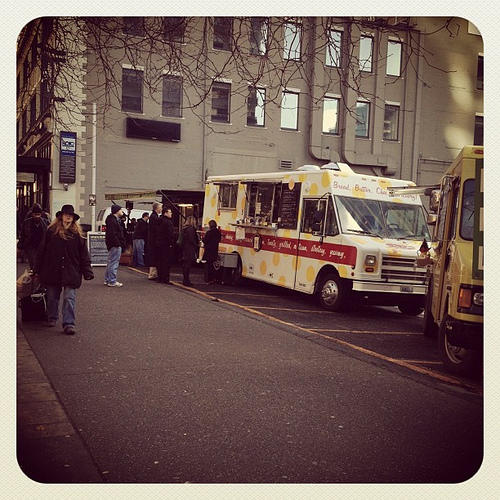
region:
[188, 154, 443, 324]
truck on the ground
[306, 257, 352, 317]
front wheel of a vehicle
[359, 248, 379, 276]
front headlight of a vehicle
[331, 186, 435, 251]
front windshield on a vehicle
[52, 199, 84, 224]
black hat on a persons head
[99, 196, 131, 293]
person with blue pants standing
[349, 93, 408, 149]
windows on a building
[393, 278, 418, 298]
front licence plate on a vehicle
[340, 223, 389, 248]
windshield wiper on a vehicle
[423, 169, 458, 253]
side rear view mirror on a vehicle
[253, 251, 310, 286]
yellow polkadots design on van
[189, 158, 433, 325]
the food vendor van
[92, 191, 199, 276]
a crowd of people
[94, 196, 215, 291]
a line of people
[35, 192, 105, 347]
a woman walking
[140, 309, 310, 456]
the ground is asphalt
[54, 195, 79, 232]
the woman wearing a black hat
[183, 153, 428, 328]
the van has yellow pokadots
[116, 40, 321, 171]
the building behind the van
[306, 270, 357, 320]
the tire on the van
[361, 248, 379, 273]
the head light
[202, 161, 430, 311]
white and yellow truck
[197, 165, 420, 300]
white truck with yellow spots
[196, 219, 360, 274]
red painted stripe on truck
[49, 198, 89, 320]
woman wearing black hat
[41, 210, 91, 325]
woman with long blond hair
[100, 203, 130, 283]
man standing in line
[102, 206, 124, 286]
man wearing blue jeans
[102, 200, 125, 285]
man wearing black beanie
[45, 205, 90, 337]
woman walking on concrete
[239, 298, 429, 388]
yellow lines painted on concrete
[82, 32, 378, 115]
low hanging tree branches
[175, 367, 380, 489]
black asphalt walkway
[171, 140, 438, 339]
a white and yellow food truck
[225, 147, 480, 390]
two parked food trucks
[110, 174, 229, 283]
a line of people waiting at a food truck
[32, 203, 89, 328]
a woman in a black hat and coat with rolling luggage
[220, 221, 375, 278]
a red stripe along the side of a food truck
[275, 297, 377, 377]
yellow painted parking lines on the asphalt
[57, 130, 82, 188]
a blue white and black sign on the corner of a building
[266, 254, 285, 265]
a yellow polka dot on the side of a food truck